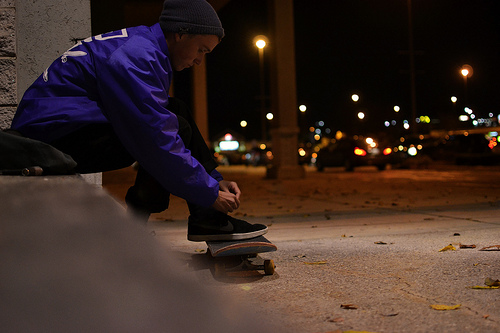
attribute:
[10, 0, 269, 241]
man — sitting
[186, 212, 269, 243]
shoe — black, white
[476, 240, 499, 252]
leaf — brown, yellow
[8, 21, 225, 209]
jacket — purple, white, blue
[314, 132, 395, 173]
vehicle — on road, on street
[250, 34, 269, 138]
street light — existing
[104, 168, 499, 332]
sidewalk — concrete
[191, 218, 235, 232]
logo — white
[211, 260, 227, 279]
wheel — brown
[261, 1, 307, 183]
pillar — stone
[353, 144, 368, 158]
tail light — red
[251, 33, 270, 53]
light — shining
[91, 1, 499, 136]
sky — black